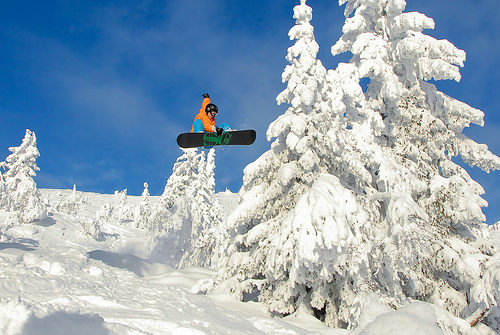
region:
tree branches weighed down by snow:
[261, 13, 457, 310]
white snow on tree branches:
[278, 181, 420, 263]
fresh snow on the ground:
[65, 241, 196, 306]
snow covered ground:
[40, 184, 172, 311]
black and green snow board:
[142, 115, 289, 161]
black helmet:
[205, 99, 225, 119]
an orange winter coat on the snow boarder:
[185, 98, 229, 132]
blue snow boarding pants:
[193, 110, 236, 135]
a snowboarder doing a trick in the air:
[141, 49, 281, 186]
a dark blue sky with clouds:
[61, 34, 198, 136]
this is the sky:
[8, 7, 90, 62]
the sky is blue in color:
[28, 5, 75, 24]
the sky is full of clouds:
[133, 7, 256, 96]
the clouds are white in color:
[230, 47, 258, 97]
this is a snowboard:
[176, 128, 263, 149]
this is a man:
[177, 90, 226, 130]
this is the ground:
[71, 277, 175, 326]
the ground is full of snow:
[99, 280, 174, 320]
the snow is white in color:
[165, 290, 217, 325]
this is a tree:
[260, 7, 485, 291]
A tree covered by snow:
[275, 11, 367, 313]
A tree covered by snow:
[366, 2, 494, 270]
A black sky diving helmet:
[205, 103, 219, 118]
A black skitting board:
[183, 129, 251, 146]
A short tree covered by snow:
[2, 141, 49, 232]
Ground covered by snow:
[64, 231, 175, 333]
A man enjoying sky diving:
[175, 72, 257, 156]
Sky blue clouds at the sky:
[44, 29, 152, 153]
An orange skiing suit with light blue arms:
[188, 91, 219, 132]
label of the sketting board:
[204, 131, 232, 145]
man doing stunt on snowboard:
[171, 82, 259, 154]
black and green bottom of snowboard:
[175, 127, 260, 149]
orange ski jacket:
[190, 96, 217, 134]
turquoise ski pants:
[192, 117, 230, 131]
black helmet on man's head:
[202, 100, 222, 121]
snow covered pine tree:
[269, 26, 384, 301]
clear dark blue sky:
[30, 26, 152, 138]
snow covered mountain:
[84, 256, 300, 333]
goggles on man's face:
[207, 108, 217, 120]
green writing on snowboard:
[199, 130, 237, 150]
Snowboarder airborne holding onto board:
[171, 88, 257, 159]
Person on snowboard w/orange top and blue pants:
[175, 91, 252, 146]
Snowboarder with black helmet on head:
[178, 90, 260, 148]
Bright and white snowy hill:
[37, 227, 196, 333]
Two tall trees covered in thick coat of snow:
[254, 1, 494, 331]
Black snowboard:
[176, 129, 258, 146]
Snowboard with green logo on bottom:
[175, 130, 258, 147]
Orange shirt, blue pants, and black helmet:
[189, 92, 236, 132]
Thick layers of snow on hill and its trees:
[0, 145, 490, 319]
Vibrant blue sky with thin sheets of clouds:
[1, 0, 226, 90]